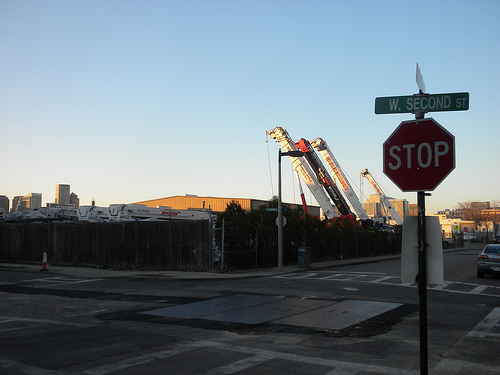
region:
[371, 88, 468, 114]
w. second st sign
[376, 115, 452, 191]
red octagonal sign with white block lettering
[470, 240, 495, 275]
rear end of a pewter toyota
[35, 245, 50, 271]
orange cone with white reflective tape around it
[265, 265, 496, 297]
white crosswalk that is fading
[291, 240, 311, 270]
dark gray plastic garbage can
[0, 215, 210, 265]
long wooden fence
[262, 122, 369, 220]
three broken cherry pickers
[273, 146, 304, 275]
street light on the sidewalk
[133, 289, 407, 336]
three metal hole covers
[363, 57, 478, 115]
Street signs at intersection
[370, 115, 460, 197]
Stop sign at city intersection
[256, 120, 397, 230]
Parked construction cranes in warehouse yard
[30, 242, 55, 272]
Orange safety cone on street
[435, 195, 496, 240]
Building in the distance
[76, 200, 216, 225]
Construction cranes with lowered booms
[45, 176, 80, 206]
Tall buildings in distance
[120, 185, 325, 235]
Construction warehouse building behind cranes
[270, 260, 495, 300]
City street crosswalk stripes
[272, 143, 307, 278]
Street light and traffic signs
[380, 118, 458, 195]
Red and white stop sign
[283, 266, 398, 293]
Large section of white crosswalk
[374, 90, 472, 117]
A green and white street sign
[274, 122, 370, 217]
Group of crains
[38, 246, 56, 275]
Small orange caution cone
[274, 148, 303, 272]
Large grey light pole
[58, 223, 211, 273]
Long brown privacy fence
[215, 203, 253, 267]
Large green shrubs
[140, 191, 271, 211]
Large metal building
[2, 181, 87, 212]
Large building in the distance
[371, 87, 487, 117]
a green street sign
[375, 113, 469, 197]
a red and white stop sign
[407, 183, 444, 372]
a metal sign post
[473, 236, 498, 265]
a silver car on the road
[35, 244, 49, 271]
an orange and white cone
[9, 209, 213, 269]
a brown wood fence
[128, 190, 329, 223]
a large brown building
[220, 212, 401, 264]
a chain link fence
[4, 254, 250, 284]
a concrete sidewalk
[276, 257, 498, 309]
a crosswalk on a road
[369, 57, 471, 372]
Stop sign at street crossing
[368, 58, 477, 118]
Street names on top of stop sign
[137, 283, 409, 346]
Metal plates covering street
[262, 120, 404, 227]
Four big construction cranes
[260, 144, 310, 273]
Grey city streetlamp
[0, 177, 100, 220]
Buildings in the distance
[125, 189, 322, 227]
Brown construction company warehouse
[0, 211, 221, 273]
Brown security fence around business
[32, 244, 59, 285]
Orange and white traffic cone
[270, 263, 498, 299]
White crosswalk for pedestrians